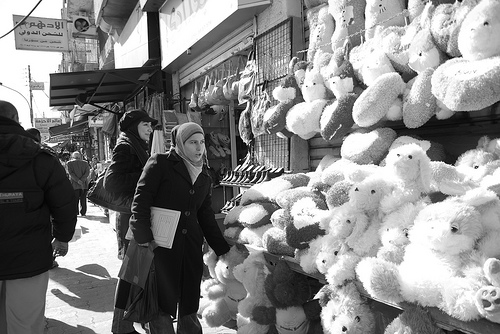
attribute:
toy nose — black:
[351, 184, 362, 194]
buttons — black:
[174, 174, 201, 250]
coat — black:
[1, 121, 76, 276]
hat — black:
[119, 106, 152, 124]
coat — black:
[116, 147, 231, 321]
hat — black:
[112, 104, 164, 126]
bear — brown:
[252, 271, 321, 331]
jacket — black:
[1, 115, 78, 281]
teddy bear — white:
[354, 185, 497, 324]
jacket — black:
[126, 150, 226, 317]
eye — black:
[352, 316, 364, 323]